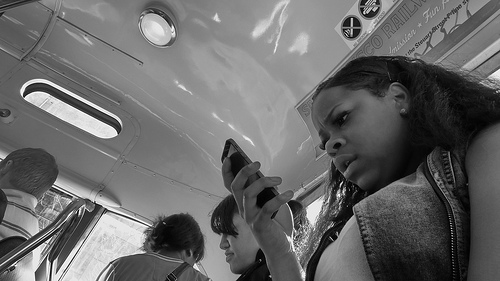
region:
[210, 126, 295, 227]
woman is holding phone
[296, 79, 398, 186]
womans face looks distraught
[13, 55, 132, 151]
small oval window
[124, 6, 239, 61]
a small circular light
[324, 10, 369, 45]
a no smoking sign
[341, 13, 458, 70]
a black and white sign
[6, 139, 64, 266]
a man with stripe shirt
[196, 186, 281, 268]
a woman with black hair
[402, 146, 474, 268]
woman wearing jean jacket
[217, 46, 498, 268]
a woman looking at her cell phone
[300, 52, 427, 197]
a woman with a surprised look on her face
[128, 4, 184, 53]
a light on the roof of a bus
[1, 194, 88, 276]
a hand rail on a bus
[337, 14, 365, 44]
a no smoking sign on a bus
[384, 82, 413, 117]
the ear of a woman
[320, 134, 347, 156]
the nose of a woman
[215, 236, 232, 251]
the nose of a woman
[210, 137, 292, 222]
a cellphone being held by a woman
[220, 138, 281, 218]
iphone in a woman's hand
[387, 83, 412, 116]
a woman's pierced ear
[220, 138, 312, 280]
phone held by woman's hand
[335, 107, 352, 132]
a woman's left eye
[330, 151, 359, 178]
a woman's open mouth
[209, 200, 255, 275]
face of a woman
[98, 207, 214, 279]
back of a person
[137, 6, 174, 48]
light in a bus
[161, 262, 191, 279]
strap on a bag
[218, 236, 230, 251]
nose on a woman's face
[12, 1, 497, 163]
curved and shiny roof of bus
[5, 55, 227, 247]
oval panel on wall above windshield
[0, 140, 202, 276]
angled bar between two people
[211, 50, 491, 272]
woman looking at cell phone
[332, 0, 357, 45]
slash over drawing of cigarette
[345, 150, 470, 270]
zipper on edge of denim garment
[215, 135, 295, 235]
fingers curled around cell phone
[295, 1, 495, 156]
rectangular advertisement behind woman's head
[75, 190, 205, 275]
woman in front of glass window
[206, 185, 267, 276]
passenger with bangs covering eyes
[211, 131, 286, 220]
black cell phone in hand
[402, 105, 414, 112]
earring in woman's ear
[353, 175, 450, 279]
jean jacket on woman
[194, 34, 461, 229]
staring at a phone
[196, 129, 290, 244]
hand holding phone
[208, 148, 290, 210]
fingers on phone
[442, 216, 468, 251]
metal zipper on jacket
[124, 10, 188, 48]
white light on the ceiling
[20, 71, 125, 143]
window on front of bus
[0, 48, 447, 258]
people riding a bus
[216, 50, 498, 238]
A woman looking at her cell phone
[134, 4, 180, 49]
a light fixture on the ceiling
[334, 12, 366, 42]
A no smoking sign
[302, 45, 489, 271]
A girl wearing a jean vest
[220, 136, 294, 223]
A hand holding a cell phone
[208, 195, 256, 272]
Person with bangs in their face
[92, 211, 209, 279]
Person preparing to leave the bus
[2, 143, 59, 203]
the back of a man's head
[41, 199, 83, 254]
a handrail on the bus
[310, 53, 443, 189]
A girl with a troubled look on her face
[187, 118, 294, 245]
Woman looking at her phone on the bus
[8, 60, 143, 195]
Small oval window near the top of the bus